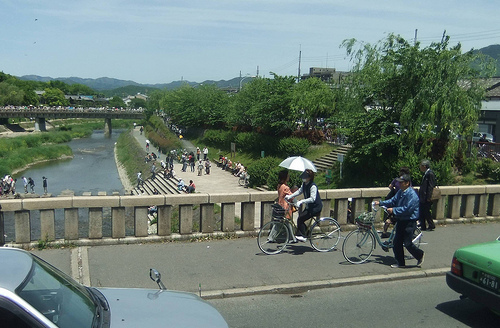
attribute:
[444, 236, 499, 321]
car — green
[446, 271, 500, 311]
bumper — black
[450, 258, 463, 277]
tail light — red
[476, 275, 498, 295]
license plate — white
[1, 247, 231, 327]
car — silver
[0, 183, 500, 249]
safety railing — concrete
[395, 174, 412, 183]
cap — black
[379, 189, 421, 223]
jacket — blue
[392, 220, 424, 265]
pants — black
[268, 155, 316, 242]
woman — walking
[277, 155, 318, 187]
umbrella — blue, white, silver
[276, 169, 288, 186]
hair — dark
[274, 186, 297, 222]
tunic — orange, pink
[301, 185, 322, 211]
vest — black, dark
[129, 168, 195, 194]
stairs — concrete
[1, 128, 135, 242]
river — narrow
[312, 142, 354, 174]
stairs — concrete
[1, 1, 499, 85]
sky — pale blue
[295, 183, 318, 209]
sleeve — white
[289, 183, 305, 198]
sleeve — white